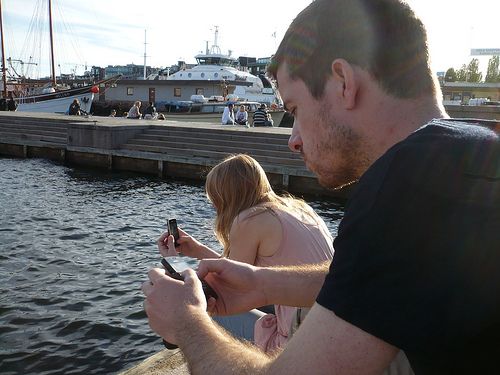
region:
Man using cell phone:
[137, 5, 499, 366]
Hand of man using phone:
[139, 263, 208, 350]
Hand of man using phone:
[185, 252, 262, 317]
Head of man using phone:
[261, 4, 459, 196]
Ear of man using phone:
[328, 58, 364, 113]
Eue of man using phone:
[282, 103, 307, 125]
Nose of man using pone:
[284, 118, 303, 160]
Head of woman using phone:
[205, 153, 279, 222]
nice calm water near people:
[42, 204, 110, 244]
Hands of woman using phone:
[148, 217, 198, 253]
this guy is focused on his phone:
[156, 250, 226, 313]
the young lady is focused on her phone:
[161, 212, 188, 252]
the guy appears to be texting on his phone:
[159, 250, 222, 307]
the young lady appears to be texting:
[162, 211, 186, 249]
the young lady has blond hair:
[200, 150, 289, 258]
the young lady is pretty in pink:
[228, 191, 342, 356]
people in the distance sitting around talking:
[63, 92, 279, 130]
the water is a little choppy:
[1, 151, 209, 371]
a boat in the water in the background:
[153, 91, 290, 128]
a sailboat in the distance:
[0, 72, 125, 114]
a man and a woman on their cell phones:
[144, 0, 497, 368]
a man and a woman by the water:
[131, 4, 497, 374]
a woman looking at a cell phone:
[153, 160, 298, 260]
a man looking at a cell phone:
[134, 9, 497, 311]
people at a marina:
[58, 8, 497, 374]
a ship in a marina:
[2, 6, 121, 110]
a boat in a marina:
[0, 6, 117, 111]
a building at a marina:
[112, 70, 240, 114]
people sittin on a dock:
[66, 95, 283, 127]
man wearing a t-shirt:
[325, 109, 492, 367]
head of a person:
[256, 6, 467, 234]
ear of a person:
[325, 61, 360, 113]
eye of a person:
[282, 101, 303, 115]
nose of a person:
[275, 116, 303, 148]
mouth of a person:
[303, 149, 323, 187]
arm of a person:
[259, 235, 346, 312]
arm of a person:
[243, 299, 385, 373]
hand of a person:
[129, 258, 214, 348]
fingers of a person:
[127, 272, 171, 336]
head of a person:
[195, 153, 277, 223]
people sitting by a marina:
[69, 98, 291, 126]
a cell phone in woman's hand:
[168, 217, 180, 248]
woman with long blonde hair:
[205, 152, 324, 257]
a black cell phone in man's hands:
[160, 255, 220, 304]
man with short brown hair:
[263, 0, 439, 190]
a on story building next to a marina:
[104, 78, 254, 107]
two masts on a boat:
[1, 0, 57, 99]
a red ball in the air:
[91, 85, 99, 93]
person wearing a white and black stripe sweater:
[253, 103, 271, 128]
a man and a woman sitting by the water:
[143, 0, 499, 372]